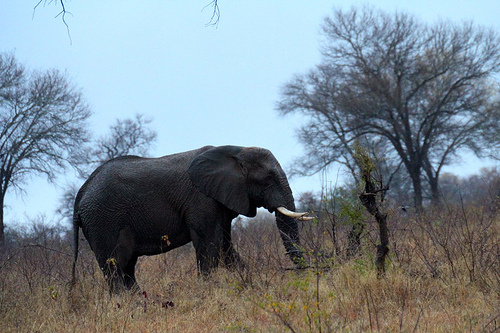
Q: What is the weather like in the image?
A: It is clear.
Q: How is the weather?
A: It is clear.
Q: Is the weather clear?
A: Yes, it is clear.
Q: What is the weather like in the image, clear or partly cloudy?
A: It is clear.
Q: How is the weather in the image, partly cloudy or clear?
A: It is clear.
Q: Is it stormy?
A: No, it is clear.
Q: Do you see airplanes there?
A: No, there are no airplanes.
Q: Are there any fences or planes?
A: No, there are no planes or fences.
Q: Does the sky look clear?
A: Yes, the sky is clear.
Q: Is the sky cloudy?
A: No, the sky is clear.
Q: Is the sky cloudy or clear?
A: The sky is clear.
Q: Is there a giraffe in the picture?
A: No, there are no giraffes.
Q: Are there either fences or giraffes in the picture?
A: No, there are no giraffes or fences.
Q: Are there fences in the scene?
A: No, there are no fences.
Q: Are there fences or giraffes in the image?
A: No, there are no fences or giraffes.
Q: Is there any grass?
A: Yes, there is grass.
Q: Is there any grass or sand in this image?
A: Yes, there is grass.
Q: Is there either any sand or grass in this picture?
A: Yes, there is grass.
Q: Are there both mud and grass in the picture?
A: No, there is grass but no mud.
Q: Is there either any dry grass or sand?
A: Yes, there is dry grass.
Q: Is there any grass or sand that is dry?
A: Yes, the grass is dry.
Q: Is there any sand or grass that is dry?
A: Yes, the grass is dry.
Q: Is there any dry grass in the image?
A: Yes, there is dry grass.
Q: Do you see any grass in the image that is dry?
A: Yes, there is grass that is dry.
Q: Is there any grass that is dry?
A: Yes, there is grass that is dry.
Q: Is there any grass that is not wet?
A: Yes, there is dry grass.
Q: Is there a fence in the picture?
A: No, there are no fences.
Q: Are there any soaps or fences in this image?
A: No, there are no fences or soaps.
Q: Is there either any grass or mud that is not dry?
A: No, there is grass but it is dry.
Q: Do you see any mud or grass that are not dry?
A: No, there is grass but it is dry.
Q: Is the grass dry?
A: Yes, the grass is dry.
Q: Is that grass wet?
A: No, the grass is dry.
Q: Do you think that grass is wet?
A: No, the grass is dry.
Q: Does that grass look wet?
A: No, the grass is dry.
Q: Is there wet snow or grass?
A: No, there is grass but it is dry.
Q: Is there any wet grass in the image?
A: No, there is grass but it is dry.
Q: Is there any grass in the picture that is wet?
A: No, there is grass but it is dry.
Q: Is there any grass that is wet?
A: No, there is grass but it is dry.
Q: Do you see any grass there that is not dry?
A: No, there is grass but it is dry.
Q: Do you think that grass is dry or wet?
A: The grass is dry.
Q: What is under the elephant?
A: The grass is under the elephant.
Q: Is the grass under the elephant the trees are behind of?
A: Yes, the grass is under the elephant.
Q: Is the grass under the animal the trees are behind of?
A: Yes, the grass is under the elephant.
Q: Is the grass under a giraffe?
A: No, the grass is under the elephant.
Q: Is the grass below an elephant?
A: Yes, the grass is below an elephant.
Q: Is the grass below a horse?
A: No, the grass is below an elephant.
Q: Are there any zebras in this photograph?
A: No, there are no zebras.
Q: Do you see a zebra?
A: No, there are no zebras.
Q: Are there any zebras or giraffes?
A: No, there are no zebras or giraffes.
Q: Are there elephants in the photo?
A: Yes, there is an elephant.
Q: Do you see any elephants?
A: Yes, there is an elephant.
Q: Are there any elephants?
A: Yes, there is an elephant.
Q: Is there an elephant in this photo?
A: Yes, there is an elephant.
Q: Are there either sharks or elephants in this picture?
A: Yes, there is an elephant.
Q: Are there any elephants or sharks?
A: Yes, there is an elephant.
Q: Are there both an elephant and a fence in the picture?
A: No, there is an elephant but no fences.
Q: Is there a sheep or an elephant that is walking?
A: Yes, the elephant is walking.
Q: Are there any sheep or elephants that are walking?
A: Yes, the elephant is walking.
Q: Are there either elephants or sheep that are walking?
A: Yes, the elephant is walking.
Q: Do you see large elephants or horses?
A: Yes, there is a large elephant.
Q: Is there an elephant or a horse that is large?
A: Yes, the elephant is large.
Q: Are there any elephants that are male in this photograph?
A: Yes, there is a male elephant.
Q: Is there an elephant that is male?
A: Yes, there is an elephant that is male.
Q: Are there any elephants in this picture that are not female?
A: Yes, there is a male elephant.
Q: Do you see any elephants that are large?
A: Yes, there is a large elephant.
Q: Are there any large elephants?
A: Yes, there is a large elephant.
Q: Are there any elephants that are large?
A: Yes, there is an elephant that is large.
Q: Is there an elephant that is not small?
A: Yes, there is a large elephant.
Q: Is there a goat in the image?
A: No, there are no goats.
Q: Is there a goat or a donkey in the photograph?
A: No, there are no goats or donkeys.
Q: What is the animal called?
A: The animal is an elephant.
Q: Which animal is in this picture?
A: The animal is an elephant.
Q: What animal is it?
A: The animal is an elephant.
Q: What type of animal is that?
A: This is an elephant.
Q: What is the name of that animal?
A: This is an elephant.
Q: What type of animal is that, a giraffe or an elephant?
A: This is an elephant.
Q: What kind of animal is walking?
A: The animal is an elephant.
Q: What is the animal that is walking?
A: The animal is an elephant.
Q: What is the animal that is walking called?
A: The animal is an elephant.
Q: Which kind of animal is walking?
A: The animal is an elephant.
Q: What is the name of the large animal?
A: The animal is an elephant.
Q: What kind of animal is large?
A: The animal is an elephant.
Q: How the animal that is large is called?
A: The animal is an elephant.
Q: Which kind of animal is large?
A: The animal is an elephant.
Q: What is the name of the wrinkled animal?
A: The animal is an elephant.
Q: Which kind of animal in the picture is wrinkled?
A: The animal is an elephant.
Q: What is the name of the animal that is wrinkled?
A: The animal is an elephant.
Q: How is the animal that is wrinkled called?
A: The animal is an elephant.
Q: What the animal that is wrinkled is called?
A: The animal is an elephant.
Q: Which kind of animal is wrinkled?
A: The animal is an elephant.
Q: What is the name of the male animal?
A: The animal is an elephant.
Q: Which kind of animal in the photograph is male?
A: The animal is an elephant.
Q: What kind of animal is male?
A: The animal is an elephant.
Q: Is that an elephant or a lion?
A: That is an elephant.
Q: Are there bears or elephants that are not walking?
A: No, there is an elephant but he is walking.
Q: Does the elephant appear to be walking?
A: Yes, the elephant is walking.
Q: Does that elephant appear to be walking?
A: Yes, the elephant is walking.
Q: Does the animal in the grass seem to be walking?
A: Yes, the elephant is walking.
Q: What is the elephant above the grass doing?
A: The elephant is walking.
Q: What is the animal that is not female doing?
A: The elephant is walking.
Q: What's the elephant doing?
A: The elephant is walking.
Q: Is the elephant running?
A: No, the elephant is walking.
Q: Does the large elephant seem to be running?
A: No, the elephant is walking.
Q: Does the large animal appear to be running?
A: No, the elephant is walking.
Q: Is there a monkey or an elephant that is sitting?
A: No, there is an elephant but he is walking.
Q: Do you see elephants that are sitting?
A: No, there is an elephant but he is walking.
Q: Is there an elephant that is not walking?
A: No, there is an elephant but he is walking.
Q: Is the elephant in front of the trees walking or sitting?
A: The elephant is walking.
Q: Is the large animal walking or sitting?
A: The elephant is walking.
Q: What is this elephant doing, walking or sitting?
A: The elephant is walking.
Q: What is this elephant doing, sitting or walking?
A: The elephant is walking.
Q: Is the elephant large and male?
A: Yes, the elephant is large and male.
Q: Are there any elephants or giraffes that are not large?
A: No, there is an elephant but he is large.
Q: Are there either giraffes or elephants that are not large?
A: No, there is an elephant but he is large.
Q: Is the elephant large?
A: Yes, the elephant is large.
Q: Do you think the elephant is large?
A: Yes, the elephant is large.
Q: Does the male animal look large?
A: Yes, the elephant is large.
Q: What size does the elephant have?
A: The elephant has large size.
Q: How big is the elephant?
A: The elephant is large.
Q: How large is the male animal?
A: The elephant is large.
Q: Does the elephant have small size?
A: No, the elephant is large.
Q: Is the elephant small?
A: No, the elephant is large.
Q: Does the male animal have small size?
A: No, the elephant is large.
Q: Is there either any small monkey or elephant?
A: No, there is an elephant but he is large.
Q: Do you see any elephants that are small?
A: No, there is an elephant but he is large.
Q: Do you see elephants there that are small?
A: No, there is an elephant but he is large.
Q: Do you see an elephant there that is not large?
A: No, there is an elephant but he is large.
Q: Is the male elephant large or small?
A: The elephant is large.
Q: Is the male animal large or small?
A: The elephant is large.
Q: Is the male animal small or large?
A: The elephant is large.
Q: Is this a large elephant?
A: Yes, this is a large elephant.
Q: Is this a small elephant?
A: No, this is a large elephant.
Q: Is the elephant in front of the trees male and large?
A: Yes, the elephant is male and large.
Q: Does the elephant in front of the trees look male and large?
A: Yes, the elephant is male and large.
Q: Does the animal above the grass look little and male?
A: No, the elephant is male but large.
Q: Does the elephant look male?
A: Yes, the elephant is male.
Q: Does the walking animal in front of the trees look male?
A: Yes, the elephant is male.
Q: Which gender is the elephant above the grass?
A: The elephant is male.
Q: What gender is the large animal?
A: The elephant is male.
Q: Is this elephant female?
A: No, the elephant is male.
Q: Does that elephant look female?
A: No, the elephant is male.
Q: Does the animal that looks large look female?
A: No, the elephant is male.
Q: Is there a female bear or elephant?
A: No, there is an elephant but he is male.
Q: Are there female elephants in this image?
A: No, there is an elephant but he is male.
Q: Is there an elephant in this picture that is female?
A: No, there is an elephant but he is male.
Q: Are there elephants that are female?
A: No, there is an elephant but he is male.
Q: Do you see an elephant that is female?
A: No, there is an elephant but he is male.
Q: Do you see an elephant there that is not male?
A: No, there is an elephant but he is male.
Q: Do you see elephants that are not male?
A: No, there is an elephant but he is male.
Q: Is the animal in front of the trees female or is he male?
A: The elephant is male.